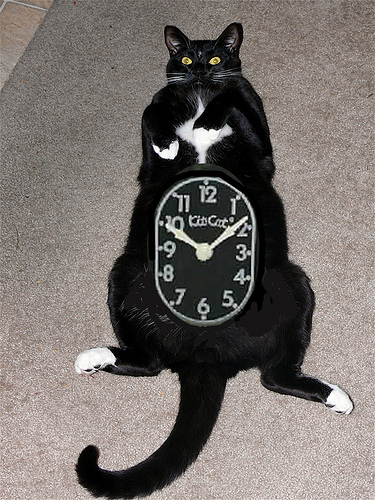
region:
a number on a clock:
[199, 178, 217, 207]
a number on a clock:
[226, 195, 239, 213]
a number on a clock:
[177, 192, 194, 210]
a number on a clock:
[234, 214, 249, 240]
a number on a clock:
[231, 257, 251, 285]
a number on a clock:
[219, 288, 236, 316]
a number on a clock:
[195, 296, 213, 318]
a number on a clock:
[171, 283, 190, 307]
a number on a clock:
[159, 258, 179, 289]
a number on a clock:
[162, 234, 181, 264]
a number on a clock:
[235, 238, 252, 264]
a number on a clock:
[224, 191, 243, 219]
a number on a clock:
[166, 213, 184, 237]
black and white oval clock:
[152, 173, 255, 324]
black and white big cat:
[47, 19, 345, 494]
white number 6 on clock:
[196, 296, 212, 322]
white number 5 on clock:
[221, 286, 236, 306]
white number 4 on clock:
[231, 267, 251, 285]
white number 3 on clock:
[235, 244, 245, 260]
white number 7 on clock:
[171, 284, 186, 306]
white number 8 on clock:
[163, 260, 175, 282]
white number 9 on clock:
[162, 240, 175, 257]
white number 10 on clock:
[165, 211, 183, 233]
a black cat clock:
[119, 1, 326, 482]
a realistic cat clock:
[89, 12, 334, 485]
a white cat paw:
[63, 336, 133, 385]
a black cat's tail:
[74, 371, 255, 499]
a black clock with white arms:
[151, 156, 276, 343]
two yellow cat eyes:
[172, 47, 232, 77]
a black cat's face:
[146, 23, 270, 90]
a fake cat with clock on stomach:
[63, 20, 326, 494]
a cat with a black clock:
[76, 25, 308, 432]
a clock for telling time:
[130, 137, 269, 332]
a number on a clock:
[233, 217, 248, 236]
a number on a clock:
[230, 264, 249, 288]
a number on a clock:
[231, 233, 250, 264]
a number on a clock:
[196, 290, 209, 318]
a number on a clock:
[219, 280, 238, 320]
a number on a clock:
[172, 280, 183, 304]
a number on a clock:
[161, 238, 176, 258]